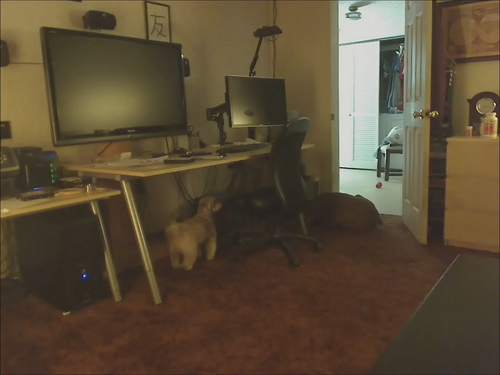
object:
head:
[197, 196, 223, 215]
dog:
[162, 195, 223, 272]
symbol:
[142, 0, 173, 43]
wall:
[0, 1, 209, 283]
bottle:
[477, 110, 497, 138]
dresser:
[442, 134, 500, 253]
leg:
[169, 248, 182, 270]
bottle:
[463, 125, 475, 138]